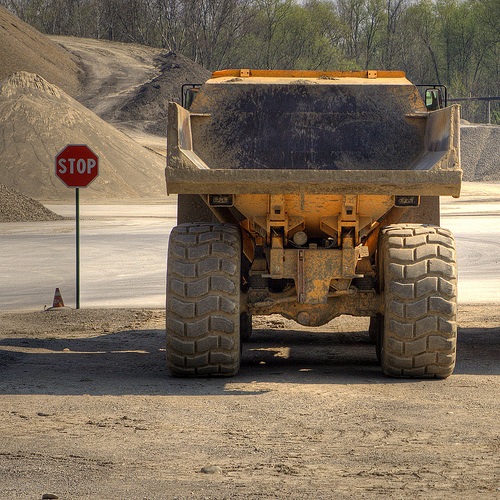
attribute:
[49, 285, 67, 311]
cone — yellow and white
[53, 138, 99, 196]
stop sign — red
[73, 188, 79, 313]
pole — metal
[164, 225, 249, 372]
tire — brown 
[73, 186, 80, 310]
pole — green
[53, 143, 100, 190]
sign — red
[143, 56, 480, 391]
truck — large, yellow, big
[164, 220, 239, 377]
wheel — large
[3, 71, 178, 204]
gravel pile — large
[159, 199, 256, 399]
tires — huge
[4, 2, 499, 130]
trees — green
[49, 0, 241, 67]
dead trees — drying out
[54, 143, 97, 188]
stop sign — octagon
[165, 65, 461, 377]
yellow truck — big yellow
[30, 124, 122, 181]
sign — red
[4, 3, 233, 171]
gravel — large pile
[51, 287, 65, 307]
cone — orange and white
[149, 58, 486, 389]
tractor — yellow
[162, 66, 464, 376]
truck — very large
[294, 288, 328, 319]
metal — yellow